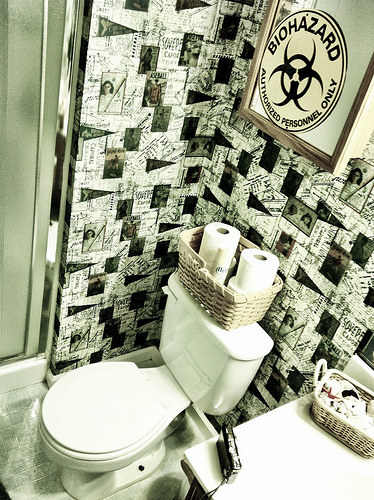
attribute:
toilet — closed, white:
[37, 270, 275, 499]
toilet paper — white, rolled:
[236, 249, 278, 294]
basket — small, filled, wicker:
[177, 224, 282, 332]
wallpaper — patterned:
[50, 0, 373, 434]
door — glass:
[0, 1, 76, 368]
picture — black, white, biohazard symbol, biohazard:
[260, 8, 347, 132]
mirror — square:
[236, 2, 373, 175]